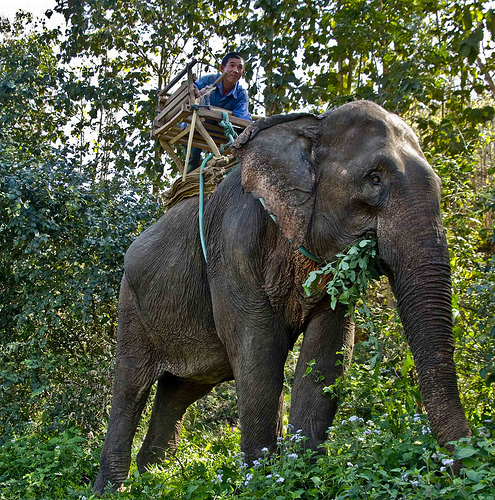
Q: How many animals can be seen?
A: 1.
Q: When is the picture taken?
A: Daytime.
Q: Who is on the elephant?
A: A man.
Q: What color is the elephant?
A: Gray.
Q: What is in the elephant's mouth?
A: Leaves.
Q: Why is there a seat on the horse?
A: For the man to ride the elephant.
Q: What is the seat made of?
A: Wood.